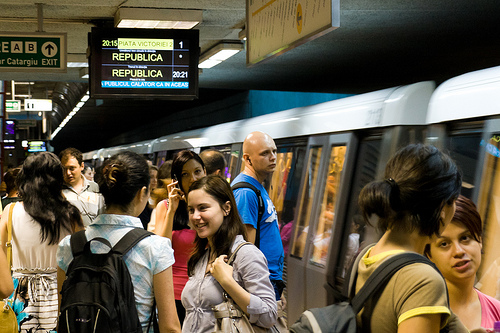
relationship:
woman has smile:
[180, 178, 271, 329] [193, 218, 216, 238]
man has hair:
[59, 152, 114, 236] [59, 148, 83, 165]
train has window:
[72, 65, 500, 332] [308, 129, 359, 267]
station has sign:
[3, 3, 480, 330] [95, 29, 201, 93]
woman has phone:
[147, 157, 219, 304] [165, 174, 196, 212]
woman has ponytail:
[63, 168, 171, 330] [101, 151, 152, 197]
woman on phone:
[147, 157, 219, 304] [165, 174, 196, 212]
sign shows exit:
[1, 26, 68, 66] [37, 39, 61, 73]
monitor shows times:
[89, 26, 193, 95] [173, 34, 192, 84]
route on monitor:
[97, 39, 175, 84] [89, 26, 193, 95]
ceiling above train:
[10, 3, 260, 71] [72, 65, 500, 332]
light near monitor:
[113, 6, 204, 34] [89, 26, 193, 95]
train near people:
[72, 65, 500, 332] [4, 141, 477, 321]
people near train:
[4, 141, 477, 321] [72, 65, 500, 332]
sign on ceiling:
[1, 26, 68, 66] [10, 3, 260, 71]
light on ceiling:
[113, 6, 204, 34] [10, 3, 260, 71]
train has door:
[72, 65, 500, 332] [287, 97, 349, 332]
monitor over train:
[89, 26, 193, 95] [72, 65, 500, 332]